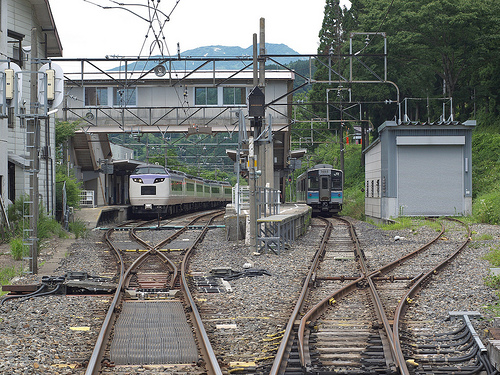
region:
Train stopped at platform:
[124, 150, 236, 227]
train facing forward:
[127, 149, 273, 230]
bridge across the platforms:
[61, 71, 282, 197]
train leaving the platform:
[291, 162, 353, 219]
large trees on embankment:
[306, 0, 496, 135]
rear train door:
[316, 173, 331, 206]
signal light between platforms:
[243, 81, 271, 136]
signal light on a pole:
[238, 82, 273, 128]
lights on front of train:
[131, 173, 176, 185]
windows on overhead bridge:
[72, 83, 262, 107]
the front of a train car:
[303, 158, 348, 215]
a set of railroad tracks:
[288, 208, 416, 347]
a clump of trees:
[315, 3, 485, 112]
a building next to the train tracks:
[1, 0, 65, 215]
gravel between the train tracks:
[202, 255, 273, 345]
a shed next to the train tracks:
[361, 123, 478, 217]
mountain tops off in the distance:
[104, 37, 297, 67]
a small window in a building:
[1, 32, 31, 64]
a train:
[127, 163, 231, 213]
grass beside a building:
[15, 202, 73, 242]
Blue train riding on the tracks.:
[291, 153, 358, 217]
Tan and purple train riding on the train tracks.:
[118, 153, 225, 225]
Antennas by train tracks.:
[96, 0, 211, 74]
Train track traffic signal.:
[13, 38, 70, 293]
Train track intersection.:
[268, 222, 411, 371]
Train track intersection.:
[87, 212, 232, 302]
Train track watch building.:
[55, 62, 317, 151]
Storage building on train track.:
[368, 75, 497, 252]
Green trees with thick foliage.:
[386, 5, 498, 102]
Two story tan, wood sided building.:
[5, 7, 63, 231]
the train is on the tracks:
[122, 160, 238, 221]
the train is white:
[115, 155, 243, 235]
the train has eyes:
[131, 171, 166, 190]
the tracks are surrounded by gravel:
[6, 208, 496, 373]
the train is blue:
[292, 163, 342, 218]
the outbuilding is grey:
[356, 112, 479, 227]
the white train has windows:
[168, 178, 235, 197]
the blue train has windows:
[295, 170, 342, 199]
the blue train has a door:
[317, 175, 333, 204]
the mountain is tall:
[105, 36, 316, 102]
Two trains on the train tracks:
[105, 150, 351, 245]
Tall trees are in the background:
[315, 0, 495, 125]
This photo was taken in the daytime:
[20, 15, 480, 360]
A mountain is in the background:
[110, 20, 306, 71]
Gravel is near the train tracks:
[30, 305, 70, 365]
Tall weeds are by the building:
[40, 205, 85, 240]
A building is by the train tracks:
[0, 0, 66, 235]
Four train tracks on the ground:
[80, 200, 480, 370]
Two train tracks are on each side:
[91, 211, 472, 371]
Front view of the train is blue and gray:
[291, 165, 350, 215]